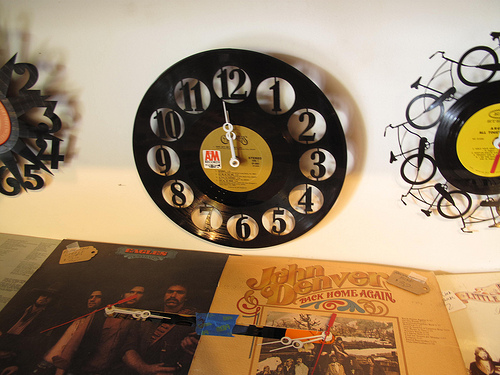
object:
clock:
[128, 45, 352, 252]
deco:
[0, 52, 67, 199]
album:
[0, 237, 228, 375]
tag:
[385, 269, 432, 296]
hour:
[212, 64, 253, 167]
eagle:
[39, 293, 139, 334]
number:
[216, 66, 249, 102]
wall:
[0, 0, 500, 273]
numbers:
[232, 215, 252, 241]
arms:
[221, 102, 241, 168]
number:
[267, 79, 283, 114]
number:
[298, 186, 314, 212]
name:
[245, 263, 390, 306]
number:
[298, 111, 316, 142]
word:
[260, 271, 390, 307]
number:
[154, 147, 173, 174]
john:
[246, 263, 325, 290]